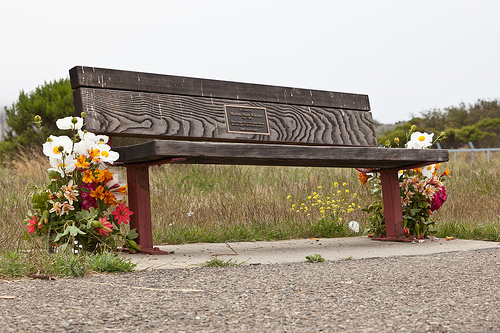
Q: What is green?
A: Grass.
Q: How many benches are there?
A: One.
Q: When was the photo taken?
A: Daytime.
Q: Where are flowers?
A: On both sides of a bench.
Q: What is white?
A: Flowers.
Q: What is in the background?
A: Trees.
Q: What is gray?
A: Ground.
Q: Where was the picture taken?
A: At a walking path.